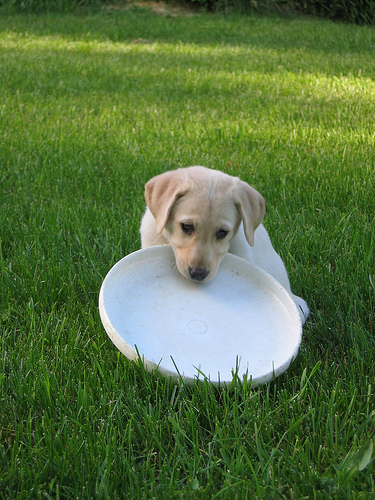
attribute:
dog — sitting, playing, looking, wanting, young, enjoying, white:
[138, 162, 309, 327]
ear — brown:
[143, 169, 189, 235]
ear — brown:
[236, 176, 264, 247]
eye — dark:
[180, 221, 194, 236]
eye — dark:
[215, 227, 229, 241]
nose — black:
[187, 263, 210, 281]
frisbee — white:
[97, 242, 303, 392]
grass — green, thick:
[0, 9, 373, 498]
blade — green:
[133, 342, 147, 379]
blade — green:
[168, 353, 186, 387]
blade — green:
[194, 364, 215, 389]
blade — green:
[216, 369, 222, 394]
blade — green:
[234, 355, 239, 395]